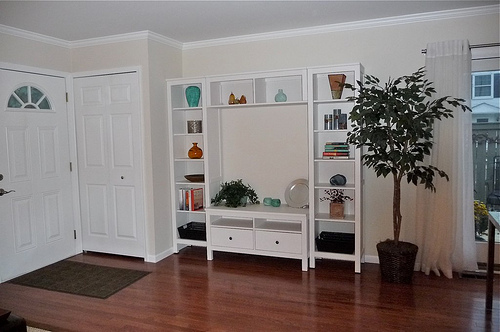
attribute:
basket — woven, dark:
[377, 238, 419, 283]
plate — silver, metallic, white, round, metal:
[286, 178, 312, 209]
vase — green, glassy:
[184, 86, 202, 107]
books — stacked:
[322, 140, 352, 158]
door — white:
[1, 62, 82, 288]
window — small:
[8, 84, 57, 111]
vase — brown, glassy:
[186, 142, 203, 158]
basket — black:
[315, 231, 355, 255]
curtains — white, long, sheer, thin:
[409, 41, 478, 279]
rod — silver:
[422, 42, 500, 55]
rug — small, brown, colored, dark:
[7, 259, 153, 300]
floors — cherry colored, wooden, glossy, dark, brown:
[2, 244, 498, 331]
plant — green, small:
[318, 188, 353, 203]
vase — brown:
[329, 201, 346, 218]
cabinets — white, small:
[209, 222, 304, 256]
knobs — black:
[228, 237, 280, 245]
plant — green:
[211, 178, 260, 206]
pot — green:
[240, 195, 247, 205]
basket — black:
[178, 221, 207, 242]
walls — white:
[2, 5, 499, 271]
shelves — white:
[165, 63, 364, 274]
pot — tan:
[328, 73, 347, 98]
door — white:
[70, 65, 150, 260]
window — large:
[471, 70, 499, 242]